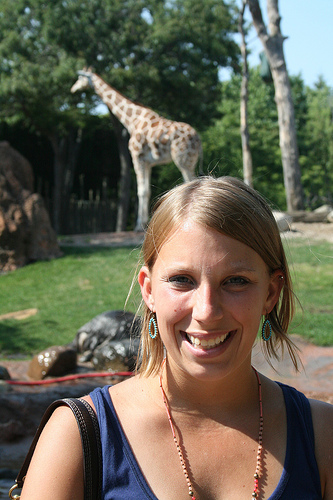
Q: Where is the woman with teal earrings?
A: Zoo.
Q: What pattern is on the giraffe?
A: Spots.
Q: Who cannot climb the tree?
A: Giraffe.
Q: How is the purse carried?
A: Strap.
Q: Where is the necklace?
A: Woman with teal earrings.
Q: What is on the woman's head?
A: Hair.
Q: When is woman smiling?
A: Right now.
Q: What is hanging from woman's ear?
A: Teal earrings.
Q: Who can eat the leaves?
A: Giraffe.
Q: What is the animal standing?
A: Giraffe.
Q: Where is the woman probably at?
A: A zoo.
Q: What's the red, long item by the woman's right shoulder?
A: A hose.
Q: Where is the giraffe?
A: In a zoo.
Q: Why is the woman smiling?
A: She's happy.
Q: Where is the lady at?
A: A zoo.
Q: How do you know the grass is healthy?
A: It's green.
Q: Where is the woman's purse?
A: On her shoulder.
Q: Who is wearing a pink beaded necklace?
A: A smiling woman.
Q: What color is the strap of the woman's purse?
A: Black.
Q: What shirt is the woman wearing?
A: A blue tank top.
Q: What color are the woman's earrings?
A: Blue.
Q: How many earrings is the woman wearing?
A: Three.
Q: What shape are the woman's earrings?
A: Oval.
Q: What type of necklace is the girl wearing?
A: A beaded necklace.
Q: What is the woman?
A: Blonde.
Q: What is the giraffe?
A: Behind the woman.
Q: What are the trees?
A: Green.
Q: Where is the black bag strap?
A: On the woman's shoulder.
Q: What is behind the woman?
A: A giraffe.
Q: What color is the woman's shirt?
A: Blue.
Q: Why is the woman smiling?
A: She's getting her picture taken.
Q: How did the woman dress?
A: For comfort.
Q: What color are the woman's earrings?
A: Blue.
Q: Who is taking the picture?
A: The woman's husband.